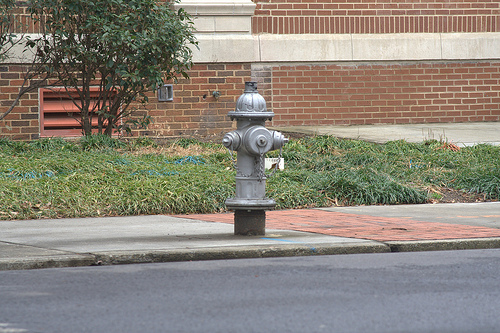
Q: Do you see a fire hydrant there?
A: Yes, there is a fire hydrant.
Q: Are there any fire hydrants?
A: Yes, there is a fire hydrant.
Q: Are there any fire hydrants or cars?
A: Yes, there is a fire hydrant.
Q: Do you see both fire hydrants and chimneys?
A: No, there is a fire hydrant but no chimneys.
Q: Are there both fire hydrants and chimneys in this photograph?
A: No, there is a fire hydrant but no chimneys.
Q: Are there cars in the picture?
A: No, there are no cars.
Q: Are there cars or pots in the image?
A: No, there are no cars or pots.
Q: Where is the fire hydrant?
A: The fire hydrant is on the sidewalk.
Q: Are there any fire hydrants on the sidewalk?
A: Yes, there is a fire hydrant on the sidewalk.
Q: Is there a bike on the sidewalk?
A: No, there is a fire hydrant on the sidewalk.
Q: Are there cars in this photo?
A: No, there are no cars.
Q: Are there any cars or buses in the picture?
A: No, there are no cars or buses.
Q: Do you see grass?
A: Yes, there is grass.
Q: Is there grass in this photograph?
A: Yes, there is grass.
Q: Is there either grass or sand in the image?
A: Yes, there is grass.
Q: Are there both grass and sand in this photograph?
A: No, there is grass but no sand.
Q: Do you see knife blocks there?
A: No, there are no knife blocks.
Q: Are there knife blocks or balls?
A: No, there are no knife blocks or balls.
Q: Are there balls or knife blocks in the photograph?
A: No, there are no knife blocks or balls.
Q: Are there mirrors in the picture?
A: No, there are no mirrors.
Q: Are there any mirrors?
A: No, there are no mirrors.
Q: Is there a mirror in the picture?
A: No, there are no mirrors.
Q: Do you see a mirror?
A: No, there are no mirrors.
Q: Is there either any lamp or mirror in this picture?
A: No, there are no mirrors or lamps.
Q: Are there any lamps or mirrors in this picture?
A: No, there are no mirrors or lamps.